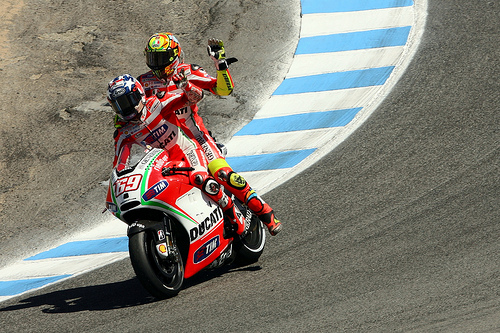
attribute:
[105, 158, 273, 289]
motorcycle — one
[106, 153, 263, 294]
motorcycle — one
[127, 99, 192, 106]
helmet —  red and yellow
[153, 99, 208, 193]
suits —  red and white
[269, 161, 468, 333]
road — black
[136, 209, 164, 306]
tire — black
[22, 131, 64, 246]
dirt — brown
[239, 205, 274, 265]
tire — black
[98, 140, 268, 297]
motorcycle — red, white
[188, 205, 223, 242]
lettering — black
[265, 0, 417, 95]
lines — blue, white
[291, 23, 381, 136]
lines — blue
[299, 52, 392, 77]
lines — white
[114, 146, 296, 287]
motorcycle — white, orange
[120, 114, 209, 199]
suit — white, orange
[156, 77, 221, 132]
suit — orange, white, yellow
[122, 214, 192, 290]
tire — black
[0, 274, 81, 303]
line —  blue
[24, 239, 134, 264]
line —  blue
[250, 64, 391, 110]
lines — blue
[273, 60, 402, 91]
line — blue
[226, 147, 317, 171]
line — blue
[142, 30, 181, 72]
helmet — ORANGE, YELLOW, SAFETY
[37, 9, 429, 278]
stripes — BLUE, WHITE